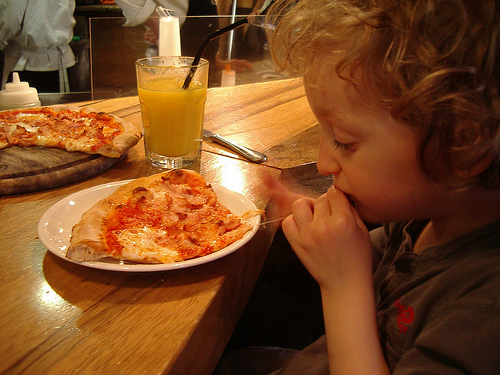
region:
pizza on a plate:
[80, 185, 227, 256]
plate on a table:
[45, 185, 171, 290]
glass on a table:
[135, 43, 210, 164]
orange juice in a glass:
[135, 48, 223, 165]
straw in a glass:
[186, 20, 259, 105]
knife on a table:
[210, 126, 260, 171]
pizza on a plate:
[50, 101, 132, 153]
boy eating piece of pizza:
[45, 30, 478, 370]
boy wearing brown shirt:
[276, 22, 493, 360]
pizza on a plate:
[7, 103, 32, 151]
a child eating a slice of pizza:
[95, 6, 482, 337]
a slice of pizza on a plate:
[65, 170, 248, 257]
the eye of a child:
[330, 126, 362, 153]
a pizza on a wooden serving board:
[0, 100, 140, 185]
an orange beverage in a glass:
[134, 8, 252, 169]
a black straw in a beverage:
[172, 15, 254, 94]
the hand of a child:
[276, 193, 378, 279]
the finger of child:
[290, 197, 315, 224]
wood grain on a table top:
[58, 300, 162, 357]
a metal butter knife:
[195, 124, 272, 165]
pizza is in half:
[108, 166, 239, 260]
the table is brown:
[41, 293, 163, 373]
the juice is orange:
[132, 59, 209, 151]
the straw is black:
[208, 12, 250, 59]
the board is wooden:
[23, 145, 80, 183]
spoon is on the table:
[213, 128, 268, 167]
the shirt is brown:
[391, 245, 498, 351]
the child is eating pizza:
[289, 154, 383, 259]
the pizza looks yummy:
[96, 169, 249, 247]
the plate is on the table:
[42, 185, 261, 272]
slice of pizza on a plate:
[34, 156, 271, 289]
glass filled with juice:
[122, 11, 258, 169]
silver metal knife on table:
[205, 127, 270, 171]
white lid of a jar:
[0, 65, 40, 108]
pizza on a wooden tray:
[0, 97, 147, 199]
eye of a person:
[332, 123, 359, 156]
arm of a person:
[267, 178, 413, 373]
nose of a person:
[312, 140, 344, 180]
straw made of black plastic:
[173, 13, 256, 90]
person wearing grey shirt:
[0, 0, 94, 92]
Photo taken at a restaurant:
[0, 1, 493, 368]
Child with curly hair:
[272, 0, 474, 367]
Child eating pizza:
[275, 0, 497, 372]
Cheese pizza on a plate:
[42, 174, 261, 271]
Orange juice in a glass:
[135, 60, 211, 170]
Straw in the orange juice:
[177, 13, 245, 92]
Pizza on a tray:
[0, 95, 133, 181]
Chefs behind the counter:
[11, 0, 217, 100]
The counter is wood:
[14, 50, 374, 366]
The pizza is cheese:
[83, 167, 261, 265]